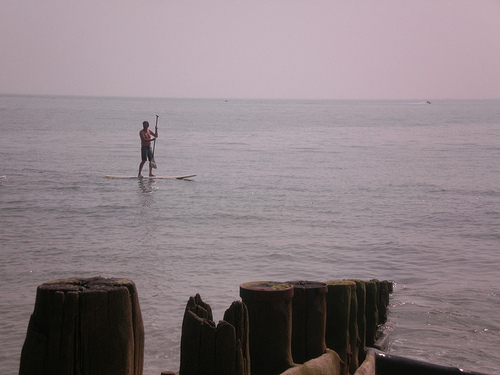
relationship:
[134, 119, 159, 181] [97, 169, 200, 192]
man on top of surfboard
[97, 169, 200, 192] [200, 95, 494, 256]
surfboard in water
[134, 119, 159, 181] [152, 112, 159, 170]
man has paddle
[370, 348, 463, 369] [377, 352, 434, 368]
trunk has edge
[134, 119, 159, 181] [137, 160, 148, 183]
man has leg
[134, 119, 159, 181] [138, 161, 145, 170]
man has knee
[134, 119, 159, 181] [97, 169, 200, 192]
man on surfboard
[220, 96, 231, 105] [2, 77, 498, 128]
boat in background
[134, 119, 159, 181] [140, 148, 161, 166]
man has shorts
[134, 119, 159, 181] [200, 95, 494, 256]
man on water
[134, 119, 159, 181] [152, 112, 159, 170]
man holding paddle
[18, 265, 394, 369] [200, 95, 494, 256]
posts leading into water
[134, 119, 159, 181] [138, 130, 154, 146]
man has bare chest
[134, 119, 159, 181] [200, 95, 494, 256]
man in water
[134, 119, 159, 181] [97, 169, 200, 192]
man floating on surfboard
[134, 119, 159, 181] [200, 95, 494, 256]
man floating on water